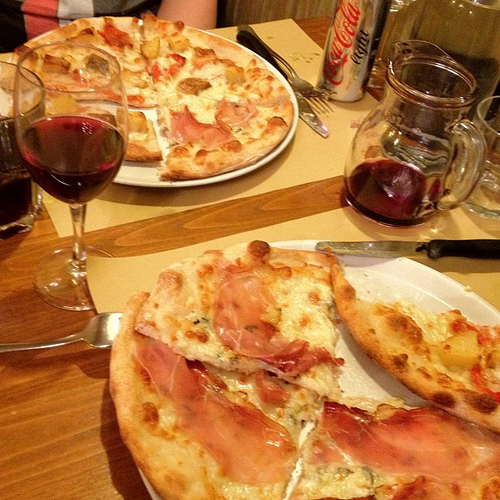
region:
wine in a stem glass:
[12, 41, 128, 312]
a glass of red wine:
[14, 41, 129, 310]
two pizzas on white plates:
[2, 18, 498, 499]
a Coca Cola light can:
[315, 0, 390, 102]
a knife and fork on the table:
[234, 22, 329, 141]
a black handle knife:
[317, 235, 498, 256]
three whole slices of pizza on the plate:
[110, 240, 499, 498]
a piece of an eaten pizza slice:
[330, 266, 499, 426]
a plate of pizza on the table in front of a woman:
[1, 1, 298, 191]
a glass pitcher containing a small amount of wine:
[342, 40, 486, 230]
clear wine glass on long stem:
[10, 38, 134, 311]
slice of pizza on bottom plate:
[130, 240, 345, 398]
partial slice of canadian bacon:
[212, 269, 305, 376]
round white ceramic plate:
[105, 234, 494, 499]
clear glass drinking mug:
[335, 48, 495, 233]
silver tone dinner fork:
[0, 308, 133, 379]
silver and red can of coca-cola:
[316, 1, 389, 103]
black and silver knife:
[315, 232, 497, 274]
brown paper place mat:
[85, 188, 497, 413]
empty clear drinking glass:
[460, 91, 499, 220]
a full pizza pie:
[115, 236, 499, 498]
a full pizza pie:
[5, 15, 297, 187]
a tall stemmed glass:
[12, 42, 127, 314]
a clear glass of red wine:
[12, 40, 128, 307]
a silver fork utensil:
[0, 310, 122, 354]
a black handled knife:
[312, 235, 499, 261]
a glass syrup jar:
[342, 37, 488, 224]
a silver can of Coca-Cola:
[313, 0, 390, 105]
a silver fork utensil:
[232, 19, 336, 101]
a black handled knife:
[238, 28, 331, 139]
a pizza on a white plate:
[4, 13, 296, 182]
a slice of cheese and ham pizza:
[139, 241, 340, 401]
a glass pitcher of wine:
[343, 35, 488, 232]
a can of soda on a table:
[318, 0, 393, 100]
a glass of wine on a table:
[13, 39, 128, 315]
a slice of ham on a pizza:
[134, 335, 295, 485]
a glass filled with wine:
[1, 60, 44, 240]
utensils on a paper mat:
[236, 21, 329, 141]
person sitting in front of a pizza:
[0, 0, 217, 52]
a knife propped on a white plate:
[315, 238, 499, 259]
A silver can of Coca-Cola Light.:
[317, 0, 376, 100]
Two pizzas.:
[16, 18, 496, 498]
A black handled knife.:
[319, 235, 496, 262]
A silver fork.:
[237, 20, 334, 100]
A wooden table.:
[0, 17, 499, 496]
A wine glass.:
[14, 40, 131, 312]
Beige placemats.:
[3, 42, 497, 382]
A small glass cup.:
[1, 59, 45, 241]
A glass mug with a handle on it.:
[342, 38, 489, 225]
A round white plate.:
[18, 17, 299, 192]